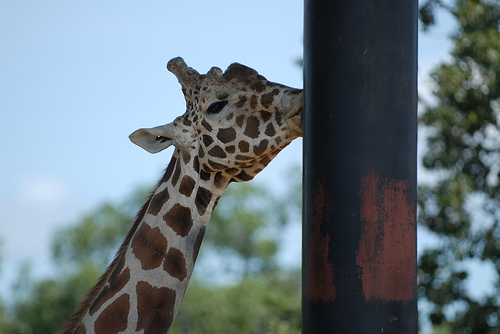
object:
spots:
[129, 281, 173, 328]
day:
[1, 0, 499, 330]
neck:
[72, 154, 235, 334]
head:
[129, 47, 303, 184]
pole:
[296, 0, 421, 334]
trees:
[216, 209, 270, 241]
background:
[0, 0, 499, 333]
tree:
[427, 37, 494, 199]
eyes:
[195, 91, 235, 121]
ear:
[126, 116, 185, 160]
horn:
[163, 52, 215, 96]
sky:
[0, 0, 308, 267]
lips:
[283, 87, 312, 135]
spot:
[164, 203, 197, 237]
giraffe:
[64, 55, 303, 333]